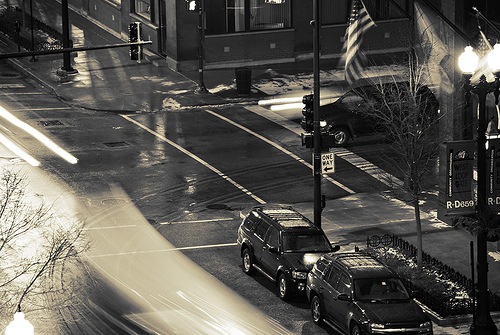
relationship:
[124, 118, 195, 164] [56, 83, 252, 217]
lines on road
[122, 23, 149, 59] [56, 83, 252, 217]
light on road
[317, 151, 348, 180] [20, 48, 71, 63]
sign on pole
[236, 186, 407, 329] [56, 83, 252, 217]
cars on road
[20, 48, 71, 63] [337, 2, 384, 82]
pole near flag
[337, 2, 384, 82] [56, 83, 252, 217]
flag on road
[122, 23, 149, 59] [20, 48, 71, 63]
light near pole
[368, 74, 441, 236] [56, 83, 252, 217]
tree on road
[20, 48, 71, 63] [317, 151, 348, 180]
pole holding sign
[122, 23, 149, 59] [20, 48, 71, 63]
light on pole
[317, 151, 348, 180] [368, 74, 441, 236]
sign near tree